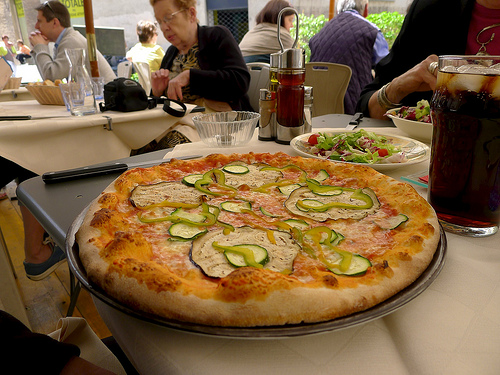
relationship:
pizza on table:
[74, 155, 442, 327] [19, 152, 497, 369]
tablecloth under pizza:
[96, 142, 500, 372] [74, 155, 442, 327]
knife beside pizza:
[44, 158, 176, 182] [74, 155, 442, 327]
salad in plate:
[306, 134, 400, 159] [289, 127, 431, 166]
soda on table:
[430, 55, 498, 235] [19, 152, 497, 369]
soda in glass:
[430, 55, 498, 235] [433, 57, 498, 233]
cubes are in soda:
[436, 62, 499, 98] [430, 55, 498, 235]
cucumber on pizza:
[229, 242, 268, 268] [74, 155, 442, 327]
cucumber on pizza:
[169, 222, 209, 242] [74, 155, 442, 327]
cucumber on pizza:
[226, 198, 251, 216] [74, 155, 442, 327]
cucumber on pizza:
[330, 252, 370, 278] [74, 155, 442, 327]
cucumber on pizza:
[226, 164, 252, 177] [74, 155, 442, 327]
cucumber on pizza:
[186, 171, 214, 190] [74, 155, 442, 327]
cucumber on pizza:
[303, 199, 326, 214] [74, 155, 442, 327]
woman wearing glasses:
[146, 2, 252, 115] [152, 11, 182, 25]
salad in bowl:
[397, 97, 432, 123] [387, 103, 436, 144]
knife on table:
[44, 158, 176, 182] [19, 152, 497, 369]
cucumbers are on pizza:
[173, 166, 405, 279] [74, 155, 442, 327]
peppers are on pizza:
[143, 169, 372, 276] [74, 155, 442, 327]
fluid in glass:
[430, 55, 498, 235] [433, 57, 498, 233]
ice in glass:
[436, 62, 499, 98] [433, 57, 498, 233]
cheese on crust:
[102, 153, 433, 291] [81, 156, 437, 325]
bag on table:
[105, 79, 187, 115] [2, 93, 197, 164]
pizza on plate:
[74, 155, 442, 327] [64, 152, 448, 339]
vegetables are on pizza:
[167, 164, 407, 278] [74, 155, 442, 327]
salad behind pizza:
[306, 134, 400, 159] [74, 155, 442, 327]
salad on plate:
[306, 134, 400, 159] [289, 127, 431, 166]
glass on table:
[433, 57, 498, 233] [19, 152, 497, 369]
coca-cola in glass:
[430, 55, 498, 235] [433, 57, 498, 233]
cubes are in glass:
[436, 62, 499, 98] [433, 57, 498, 233]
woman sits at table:
[146, 2, 252, 115] [2, 93, 197, 164]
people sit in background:
[234, 4, 386, 120] [3, 3, 499, 114]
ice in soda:
[436, 62, 499, 98] [430, 55, 498, 235]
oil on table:
[268, 51, 282, 130] [19, 152, 497, 369]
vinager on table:
[280, 49, 304, 135] [19, 152, 497, 369]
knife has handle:
[44, 158, 176, 182] [44, 165, 128, 188]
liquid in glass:
[430, 55, 498, 235] [433, 57, 498, 233]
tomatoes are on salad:
[307, 134, 392, 163] [306, 134, 400, 159]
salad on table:
[306, 134, 400, 159] [19, 152, 497, 369]